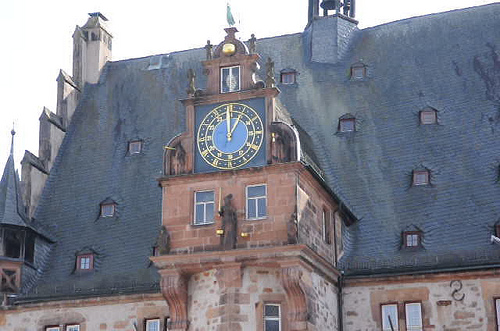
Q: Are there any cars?
A: No, there are no cars.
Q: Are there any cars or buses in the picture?
A: No, there are no cars or buses.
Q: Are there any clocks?
A: Yes, there is a clock.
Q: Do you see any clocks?
A: Yes, there is a clock.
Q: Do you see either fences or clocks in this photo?
A: Yes, there is a clock.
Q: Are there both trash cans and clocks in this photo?
A: No, there is a clock but no trash cans.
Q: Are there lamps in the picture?
A: No, there are no lamps.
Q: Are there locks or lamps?
A: No, there are no lamps or locks.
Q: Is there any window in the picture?
A: Yes, there is a window.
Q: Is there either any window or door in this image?
A: Yes, there is a window.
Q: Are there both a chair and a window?
A: No, there is a window but no chairs.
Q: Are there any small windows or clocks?
A: Yes, there is a small window.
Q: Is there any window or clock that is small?
A: Yes, the window is small.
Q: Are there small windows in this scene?
A: Yes, there is a small window.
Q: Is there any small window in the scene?
A: Yes, there is a small window.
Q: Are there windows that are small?
A: Yes, there is a window that is small.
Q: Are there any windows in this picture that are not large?
A: Yes, there is a small window.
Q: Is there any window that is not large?
A: Yes, there is a small window.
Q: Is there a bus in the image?
A: No, there are no buses.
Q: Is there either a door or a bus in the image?
A: No, there are no buses or doors.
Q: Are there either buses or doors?
A: No, there are no buses or doors.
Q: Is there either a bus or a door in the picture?
A: No, there are no buses or doors.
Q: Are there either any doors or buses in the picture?
A: No, there are no buses or doors.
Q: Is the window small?
A: Yes, the window is small.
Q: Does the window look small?
A: Yes, the window is small.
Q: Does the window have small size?
A: Yes, the window is small.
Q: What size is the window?
A: The window is small.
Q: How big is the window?
A: The window is small.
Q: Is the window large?
A: No, the window is small.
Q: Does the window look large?
A: No, the window is small.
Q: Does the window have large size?
A: No, the window is small.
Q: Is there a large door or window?
A: No, there is a window but it is small.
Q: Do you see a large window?
A: No, there is a window but it is small.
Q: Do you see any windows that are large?
A: No, there is a window but it is small.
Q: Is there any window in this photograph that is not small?
A: No, there is a window but it is small.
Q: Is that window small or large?
A: The window is small.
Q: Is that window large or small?
A: The window is small.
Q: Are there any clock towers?
A: Yes, there is a clock tower.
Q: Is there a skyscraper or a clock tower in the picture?
A: Yes, there is a clock tower.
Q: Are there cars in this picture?
A: No, there are no cars.